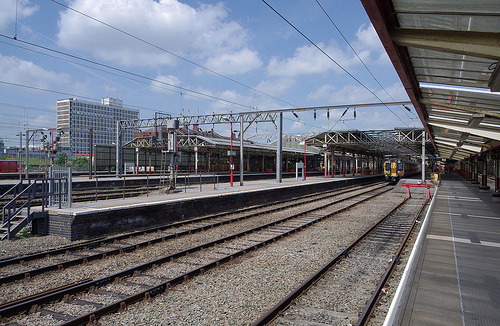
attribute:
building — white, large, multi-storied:
[50, 95, 152, 170]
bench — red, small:
[399, 181, 440, 207]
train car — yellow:
[382, 154, 424, 185]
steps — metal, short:
[0, 175, 57, 245]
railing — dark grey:
[32, 176, 68, 210]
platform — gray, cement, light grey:
[386, 166, 500, 325]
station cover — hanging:
[361, 2, 497, 164]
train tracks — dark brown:
[4, 178, 432, 325]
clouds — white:
[55, 4, 264, 83]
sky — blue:
[6, 3, 404, 137]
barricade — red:
[320, 159, 400, 179]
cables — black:
[2, 1, 416, 136]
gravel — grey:
[202, 220, 358, 309]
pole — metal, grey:
[271, 108, 291, 189]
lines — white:
[436, 182, 499, 271]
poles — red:
[222, 123, 314, 182]